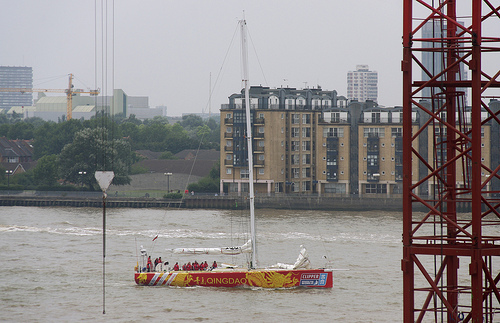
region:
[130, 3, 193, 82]
this is the sky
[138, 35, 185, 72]
the sky is blue in color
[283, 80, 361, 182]
this is a building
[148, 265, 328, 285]
this is a boat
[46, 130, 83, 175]
this is a tree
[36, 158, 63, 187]
the tree has green leaves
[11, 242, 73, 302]
this is a water zone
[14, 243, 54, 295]
the water is calm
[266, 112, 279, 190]
the wall is brown in color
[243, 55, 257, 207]
this is a pole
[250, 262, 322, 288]
this is a boat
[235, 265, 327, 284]
the boat is long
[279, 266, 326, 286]
the boat is red in color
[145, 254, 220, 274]
people are in the boat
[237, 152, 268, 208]
this is a pole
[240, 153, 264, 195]
the pole is long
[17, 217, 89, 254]
the waves are small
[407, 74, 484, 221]
the post is red in color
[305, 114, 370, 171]
this is a building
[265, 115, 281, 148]
the wall is brown in color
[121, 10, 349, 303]
a red and yellow boat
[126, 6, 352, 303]
a colorful sailboat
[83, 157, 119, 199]
a metal sign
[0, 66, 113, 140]
a bright yellow crane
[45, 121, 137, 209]
a large green tree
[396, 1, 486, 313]
a tall metal frame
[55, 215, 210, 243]
a wake in the river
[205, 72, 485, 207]
a large brown building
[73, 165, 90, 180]
a few street lights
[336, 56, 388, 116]
a tall building in distance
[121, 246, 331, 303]
yellow and red long boat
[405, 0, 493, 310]
red metal electrical tower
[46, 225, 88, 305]
gray brown ocean water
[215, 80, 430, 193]
a tan and black apartment building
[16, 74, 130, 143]
yellow crane in the background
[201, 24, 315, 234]
poles and strings attatched to boat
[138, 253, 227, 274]
several riders on the boat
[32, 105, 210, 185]
large wooded area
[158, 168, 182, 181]
small street lamp in distance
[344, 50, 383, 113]
tan hotel building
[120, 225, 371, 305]
A boat in the water.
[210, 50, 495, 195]
A building on the other side of the water.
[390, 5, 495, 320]
The structure is red.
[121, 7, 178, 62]
The sky is gray.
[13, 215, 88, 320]
The water is brown.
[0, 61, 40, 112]
A tall building in the distance.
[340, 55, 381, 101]
Another tall building in the distance.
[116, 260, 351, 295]
The boat has red and yellow on it.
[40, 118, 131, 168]
Trees growing near the water.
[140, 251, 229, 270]
People on the boat.